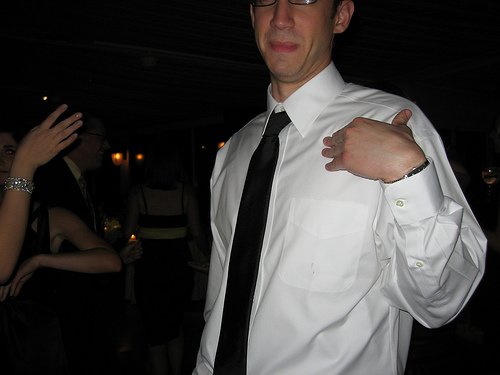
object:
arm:
[354, 96, 486, 331]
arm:
[200, 238, 225, 325]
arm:
[0, 163, 38, 284]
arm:
[36, 206, 124, 277]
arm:
[183, 195, 211, 243]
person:
[111, 154, 209, 277]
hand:
[320, 106, 428, 186]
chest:
[213, 144, 380, 298]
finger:
[321, 135, 346, 148]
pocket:
[273, 194, 371, 296]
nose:
[266, 1, 297, 33]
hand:
[9, 102, 84, 170]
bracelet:
[0, 176, 36, 196]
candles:
[108, 152, 124, 168]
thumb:
[389, 107, 414, 131]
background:
[0, 0, 498, 374]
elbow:
[0, 264, 17, 285]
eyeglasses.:
[246, 0, 322, 10]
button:
[394, 199, 403, 208]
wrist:
[4, 169, 33, 198]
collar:
[257, 62, 344, 140]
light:
[110, 152, 125, 165]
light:
[134, 152, 142, 162]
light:
[126, 233, 139, 245]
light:
[100, 225, 108, 233]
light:
[39, 93, 47, 103]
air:
[7, 3, 183, 84]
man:
[190, 0, 488, 374]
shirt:
[190, 59, 488, 375]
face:
[251, 1, 336, 77]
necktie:
[211, 108, 292, 375]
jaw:
[261, 59, 302, 79]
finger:
[40, 101, 72, 130]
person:
[0, 103, 126, 305]